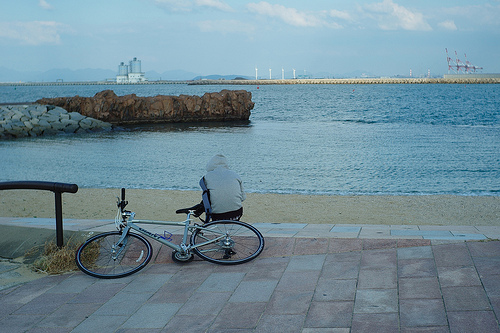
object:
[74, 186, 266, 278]
bicycle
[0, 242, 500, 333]
walkway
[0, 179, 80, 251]
railing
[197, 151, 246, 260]
person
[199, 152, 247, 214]
jacket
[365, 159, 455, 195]
water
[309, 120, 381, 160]
water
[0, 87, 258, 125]
cliff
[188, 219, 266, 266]
tires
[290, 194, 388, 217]
sand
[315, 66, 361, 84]
distance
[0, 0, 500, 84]
sky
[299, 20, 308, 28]
clouds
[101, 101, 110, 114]
rocks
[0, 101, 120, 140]
barrier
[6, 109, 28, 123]
gray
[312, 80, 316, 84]
strips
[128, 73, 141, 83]
buildings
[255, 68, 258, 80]
poles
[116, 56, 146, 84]
structure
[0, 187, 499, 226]
beach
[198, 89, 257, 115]
rock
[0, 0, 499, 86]
background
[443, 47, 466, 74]
terbines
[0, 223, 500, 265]
path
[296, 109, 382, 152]
body of water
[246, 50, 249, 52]
bird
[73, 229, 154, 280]
front tire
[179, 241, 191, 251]
petal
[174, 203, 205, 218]
seat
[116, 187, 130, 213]
handlebars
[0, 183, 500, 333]
ground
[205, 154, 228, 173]
hoodie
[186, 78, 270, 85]
pier